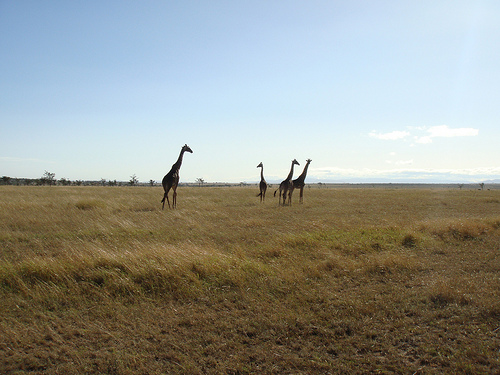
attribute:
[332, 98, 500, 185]
clouds — white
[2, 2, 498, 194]
sky — blue, clear, cloudless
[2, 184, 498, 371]
grass — brown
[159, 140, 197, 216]
plain — grassy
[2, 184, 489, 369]
plain — grassy